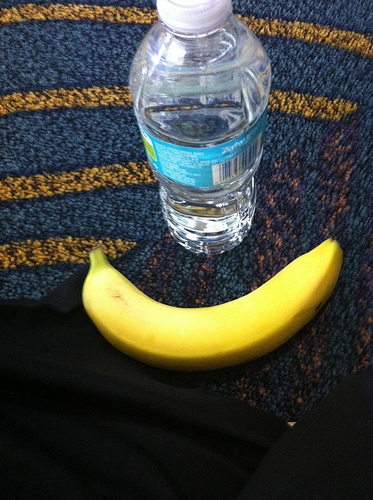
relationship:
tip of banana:
[88, 247, 109, 268] [80, 236, 343, 373]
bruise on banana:
[107, 290, 127, 307] [80, 236, 343, 373]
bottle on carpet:
[127, 1, 273, 265] [2, 1, 372, 419]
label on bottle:
[132, 108, 271, 193] [127, 1, 273, 265]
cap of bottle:
[154, 0, 233, 35] [127, 1, 273, 265]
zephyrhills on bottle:
[217, 125, 260, 155] [127, 1, 273, 265]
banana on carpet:
[80, 236, 343, 373] [2, 1, 372, 419]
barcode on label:
[211, 131, 265, 187] [132, 108, 271, 193]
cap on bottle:
[154, 0, 233, 35] [127, 1, 273, 265]